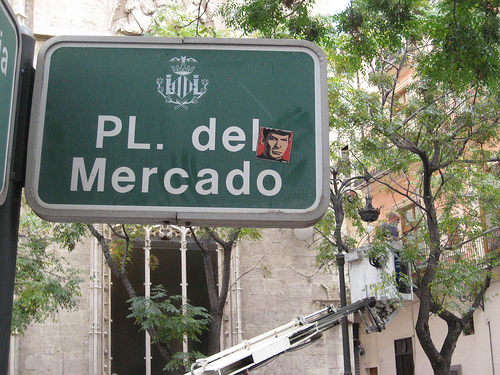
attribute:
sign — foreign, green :
[36, 26, 332, 233]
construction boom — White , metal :
[200, 286, 399, 373]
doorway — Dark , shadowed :
[98, 223, 223, 372]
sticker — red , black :
[264, 125, 294, 163]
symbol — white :
[144, 53, 212, 113]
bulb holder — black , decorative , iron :
[349, 170, 389, 230]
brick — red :
[369, 192, 403, 206]